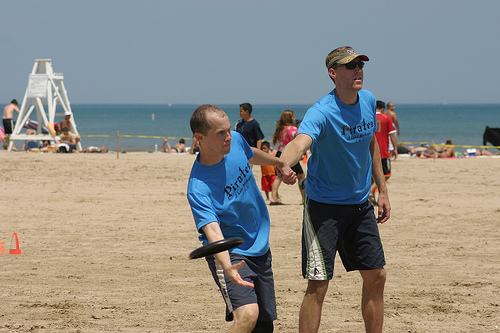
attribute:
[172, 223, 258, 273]
frisbee — black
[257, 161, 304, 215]
shorts — red